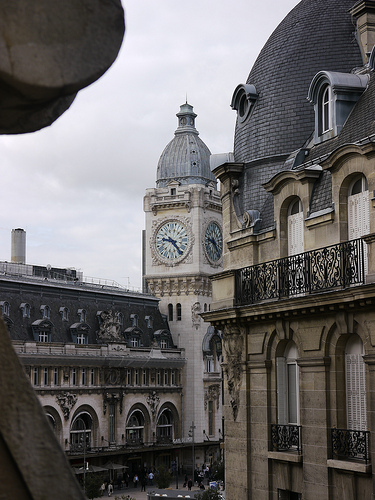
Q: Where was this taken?
A: In a town square.